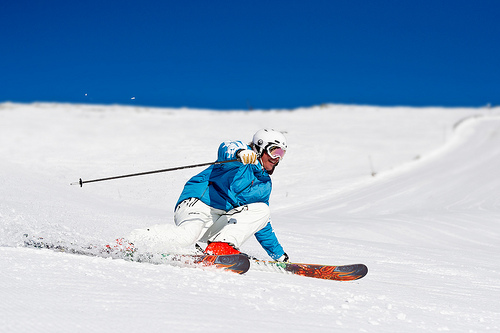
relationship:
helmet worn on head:
[251, 127, 288, 152] [251, 128, 288, 172]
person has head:
[109, 127, 292, 264] [251, 128, 288, 172]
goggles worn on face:
[265, 144, 287, 161] [265, 140, 283, 171]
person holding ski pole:
[109, 127, 292, 264] [69, 151, 262, 187]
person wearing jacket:
[109, 127, 292, 264] [174, 139, 285, 262]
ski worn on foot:
[249, 255, 370, 280] [205, 240, 249, 258]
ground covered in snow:
[1, 102, 499, 332] [1, 102, 499, 331]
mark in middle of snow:
[273, 114, 499, 212] [1, 102, 499, 331]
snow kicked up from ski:
[1, 207, 215, 268] [23, 233, 251, 275]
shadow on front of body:
[197, 160, 239, 243] [145, 145, 272, 254]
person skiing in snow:
[109, 127, 292, 264] [1, 102, 499, 331]